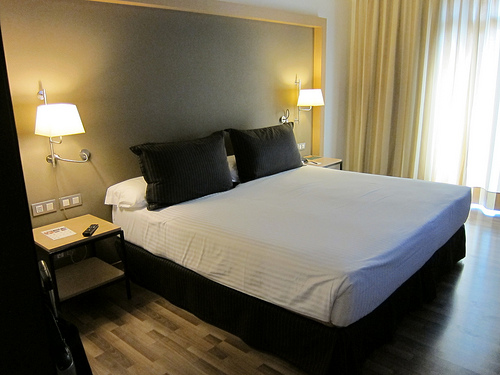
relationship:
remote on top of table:
[84, 223, 98, 237] [33, 214, 132, 316]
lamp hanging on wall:
[36, 88, 90, 169] [1, 1, 350, 230]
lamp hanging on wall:
[298, 90, 324, 112] [1, 1, 350, 230]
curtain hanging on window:
[347, 2, 500, 209] [415, 0, 499, 185]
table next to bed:
[33, 214, 132, 316] [106, 155, 473, 374]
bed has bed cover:
[106, 155, 473, 374] [112, 166, 471, 326]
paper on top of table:
[42, 227, 76, 240] [33, 214, 132, 316]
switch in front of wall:
[31, 193, 82, 218] [1, 1, 350, 230]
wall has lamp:
[1, 1, 350, 230] [36, 88, 90, 169]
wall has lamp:
[1, 1, 350, 230] [298, 90, 324, 112]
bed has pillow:
[106, 155, 473, 374] [130, 131, 237, 211]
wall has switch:
[1, 1, 350, 230] [31, 193, 82, 218]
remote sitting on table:
[84, 223, 98, 237] [33, 214, 132, 316]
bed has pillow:
[106, 155, 473, 374] [105, 177, 148, 211]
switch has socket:
[31, 193, 82, 218] [46, 203, 55, 210]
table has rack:
[33, 214, 132, 316] [54, 258, 125, 299]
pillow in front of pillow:
[130, 131, 237, 211] [105, 177, 148, 211]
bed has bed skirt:
[106, 155, 473, 374] [121, 225, 466, 373]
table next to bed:
[306, 155, 344, 167] [106, 155, 473, 374]